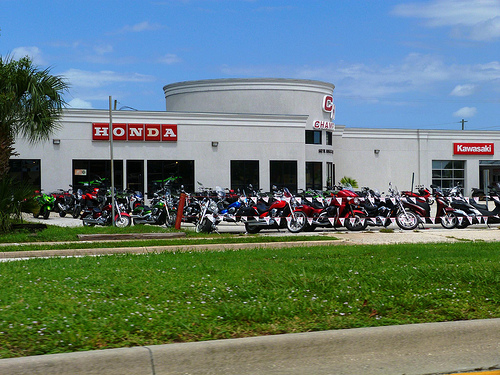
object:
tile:
[161, 124, 177, 140]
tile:
[145, 124, 159, 141]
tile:
[128, 124, 145, 139]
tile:
[111, 121, 128, 141]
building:
[0, 79, 499, 220]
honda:
[92, 122, 178, 142]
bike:
[248, 191, 315, 233]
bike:
[301, 191, 367, 229]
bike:
[354, 187, 421, 231]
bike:
[391, 182, 458, 230]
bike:
[109, 188, 175, 227]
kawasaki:
[452, 140, 494, 155]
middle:
[162, 77, 335, 120]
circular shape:
[164, 75, 338, 118]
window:
[228, 159, 263, 193]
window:
[269, 159, 297, 188]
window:
[149, 158, 195, 197]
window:
[74, 158, 127, 193]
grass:
[0, 238, 495, 355]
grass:
[0, 223, 331, 250]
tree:
[0, 55, 68, 232]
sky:
[0, 0, 498, 129]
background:
[3, 1, 498, 131]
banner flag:
[237, 194, 248, 205]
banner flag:
[250, 196, 258, 203]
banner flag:
[238, 216, 250, 226]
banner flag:
[264, 216, 272, 228]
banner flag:
[203, 213, 218, 224]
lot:
[6, 182, 496, 232]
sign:
[90, 123, 178, 142]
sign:
[448, 142, 495, 157]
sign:
[319, 91, 336, 112]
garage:
[479, 163, 499, 199]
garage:
[3, 159, 43, 205]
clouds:
[443, 1, 481, 101]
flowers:
[119, 315, 133, 323]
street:
[0, 228, 498, 374]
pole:
[172, 190, 185, 231]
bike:
[30, 191, 59, 219]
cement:
[0, 317, 497, 374]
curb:
[4, 319, 496, 374]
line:
[460, 366, 496, 375]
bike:
[196, 194, 233, 236]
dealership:
[3, 76, 495, 215]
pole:
[457, 117, 468, 130]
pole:
[113, 100, 119, 108]